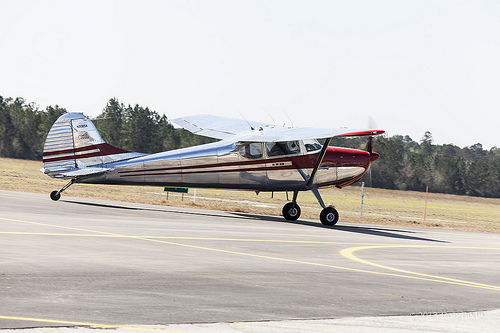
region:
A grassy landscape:
[2, 155, 497, 227]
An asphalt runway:
[5, 188, 499, 331]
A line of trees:
[2, 95, 499, 193]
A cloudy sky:
[1, 0, 497, 142]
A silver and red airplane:
[31, 105, 384, 225]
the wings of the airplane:
[171, 109, 384, 141]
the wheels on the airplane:
[36, 186, 339, 223]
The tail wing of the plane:
[28, 111, 135, 190]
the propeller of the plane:
[356, 116, 393, 200]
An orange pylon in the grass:
[417, 183, 431, 223]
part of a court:
[330, 278, 350, 300]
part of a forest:
[425, 151, 444, 163]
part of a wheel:
[331, 203, 341, 224]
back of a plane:
[61, 82, 98, 180]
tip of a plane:
[354, 145, 366, 183]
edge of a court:
[164, 252, 181, 262]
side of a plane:
[211, 156, 214, 161]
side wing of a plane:
[297, 132, 310, 137]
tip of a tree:
[120, 110, 137, 155]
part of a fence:
[400, 172, 424, 210]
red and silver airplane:
[30, 80, 420, 240]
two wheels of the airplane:
[274, 201, 337, 228]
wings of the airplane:
[173, 112, 390, 149]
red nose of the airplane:
[322, 141, 380, 186]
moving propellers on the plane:
[355, 113, 382, 216]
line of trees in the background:
[3, 97, 498, 195]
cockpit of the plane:
[230, 132, 323, 189]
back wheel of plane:
[41, 179, 71, 204]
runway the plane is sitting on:
[0, 186, 499, 326]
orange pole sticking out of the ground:
[417, 175, 439, 232]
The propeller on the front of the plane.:
[362, 127, 389, 169]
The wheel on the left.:
[280, 198, 301, 222]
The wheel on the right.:
[316, 203, 347, 229]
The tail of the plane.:
[54, 117, 104, 169]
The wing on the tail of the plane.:
[73, 165, 110, 187]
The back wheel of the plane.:
[49, 182, 65, 201]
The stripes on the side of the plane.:
[112, 151, 319, 176]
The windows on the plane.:
[249, 141, 317, 160]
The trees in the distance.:
[9, 97, 497, 207]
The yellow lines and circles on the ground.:
[10, 197, 497, 331]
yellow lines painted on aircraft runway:
[284, 235, 471, 296]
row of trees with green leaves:
[395, 139, 497, 200]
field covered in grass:
[430, 192, 499, 228]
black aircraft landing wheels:
[262, 198, 342, 228]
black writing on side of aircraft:
[263, 158, 294, 175]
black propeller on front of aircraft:
[355, 103, 385, 194]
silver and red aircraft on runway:
[32, 92, 395, 249]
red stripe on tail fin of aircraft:
[32, 129, 133, 169]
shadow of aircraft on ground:
[218, 190, 446, 266]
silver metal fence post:
[353, 180, 370, 215]